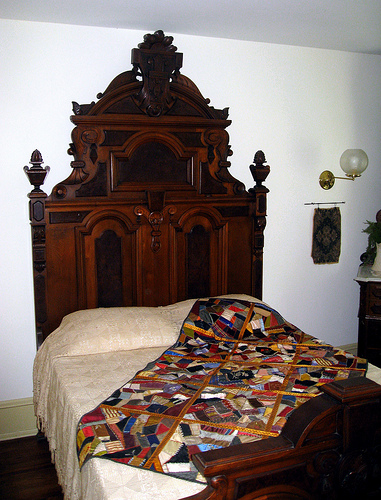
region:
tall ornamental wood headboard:
[25, 22, 277, 298]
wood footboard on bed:
[257, 378, 368, 495]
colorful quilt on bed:
[129, 323, 275, 443]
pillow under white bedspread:
[67, 301, 174, 361]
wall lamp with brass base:
[313, 144, 371, 195]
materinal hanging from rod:
[302, 195, 351, 271]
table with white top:
[347, 271, 374, 340]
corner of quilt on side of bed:
[68, 434, 89, 473]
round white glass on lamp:
[335, 144, 374, 178]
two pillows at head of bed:
[57, 289, 277, 358]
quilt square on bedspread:
[92, 409, 154, 454]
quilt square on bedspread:
[139, 379, 176, 412]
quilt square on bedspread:
[200, 392, 264, 436]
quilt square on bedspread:
[224, 362, 270, 391]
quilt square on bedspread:
[159, 351, 209, 377]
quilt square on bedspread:
[174, 329, 226, 356]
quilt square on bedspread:
[197, 293, 240, 331]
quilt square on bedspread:
[249, 309, 298, 343]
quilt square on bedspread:
[300, 343, 353, 364]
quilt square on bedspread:
[290, 364, 350, 381]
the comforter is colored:
[156, 339, 348, 424]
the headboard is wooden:
[41, 253, 263, 288]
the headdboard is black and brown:
[74, 99, 280, 289]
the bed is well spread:
[47, 311, 363, 425]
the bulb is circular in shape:
[332, 145, 373, 189]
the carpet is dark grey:
[312, 204, 356, 265]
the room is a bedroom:
[2, 11, 378, 491]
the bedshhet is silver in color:
[53, 339, 112, 415]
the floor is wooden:
[26, 439, 67, 496]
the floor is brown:
[16, 452, 56, 496]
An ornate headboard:
[20, 26, 286, 316]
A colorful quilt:
[126, 297, 280, 431]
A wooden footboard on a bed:
[184, 377, 378, 496]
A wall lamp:
[308, 134, 371, 196]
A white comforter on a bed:
[45, 293, 159, 383]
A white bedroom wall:
[231, 40, 311, 335]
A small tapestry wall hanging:
[295, 192, 357, 271]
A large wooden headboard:
[14, 28, 269, 308]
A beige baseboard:
[2, 385, 47, 450]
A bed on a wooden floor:
[4, 435, 87, 494]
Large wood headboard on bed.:
[134, 179, 198, 258]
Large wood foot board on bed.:
[276, 440, 329, 492]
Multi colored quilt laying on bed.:
[140, 378, 226, 424]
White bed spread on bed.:
[69, 354, 113, 472]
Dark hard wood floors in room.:
[20, 444, 58, 497]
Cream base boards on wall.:
[9, 403, 48, 432]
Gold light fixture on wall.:
[306, 161, 345, 215]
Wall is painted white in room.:
[276, 81, 341, 152]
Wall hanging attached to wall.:
[301, 202, 371, 285]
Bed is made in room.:
[74, 367, 191, 473]